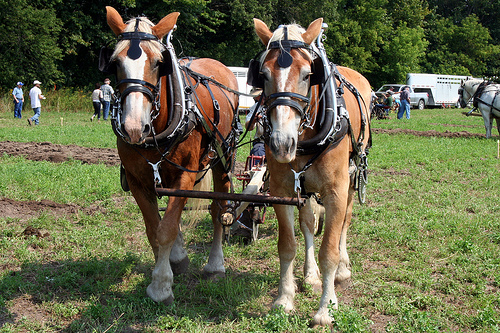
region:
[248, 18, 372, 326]
A tan and white horse.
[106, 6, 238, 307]
A brown and white horse.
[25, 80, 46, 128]
Person walking in field.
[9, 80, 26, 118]
A man wearing blue.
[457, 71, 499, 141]
A white work horse.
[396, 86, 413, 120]
A man in blue pants.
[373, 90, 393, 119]
A person sitting down.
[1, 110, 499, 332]
A green plow field.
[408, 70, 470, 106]
A white horse trailer.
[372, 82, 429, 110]
A silver colored truck.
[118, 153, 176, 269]
the brown and white leg of the horse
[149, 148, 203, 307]
the brown and white leg of the horse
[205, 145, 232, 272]
the brown and white leg of the horse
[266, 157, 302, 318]
the brown and white leg of the horse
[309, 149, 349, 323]
the brown and white leg of the horse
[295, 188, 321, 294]
the brown and white leg of the horse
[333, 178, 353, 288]
the brown and white leg of the horse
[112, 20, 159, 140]
the brown and white head of the horse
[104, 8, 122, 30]
the brown ear of the horse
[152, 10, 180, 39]
the brown ear of the horse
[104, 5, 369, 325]
draft horses pull a plow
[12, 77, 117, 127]
people walking from the field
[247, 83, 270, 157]
a man rides a plow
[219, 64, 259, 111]
a white trailer for moving horses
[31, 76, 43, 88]
man wears a white baseball cap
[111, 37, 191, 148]
both horses wear heavy padded collars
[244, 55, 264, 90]
blinkers near the eye lessens distractions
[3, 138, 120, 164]
a plowed section of land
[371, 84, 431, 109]
A pickup truck pulls a trailer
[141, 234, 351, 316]
all feet on both horses are white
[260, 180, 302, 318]
the leg of a horse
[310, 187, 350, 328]
the leg of a horse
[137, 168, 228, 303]
the legs of a horse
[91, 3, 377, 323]
two horses tied together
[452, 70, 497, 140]
a white horse in the background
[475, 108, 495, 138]
the leg of a horse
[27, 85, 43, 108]
a man in a white shirt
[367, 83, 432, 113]
a silver truck parked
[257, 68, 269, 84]
the eye of a horse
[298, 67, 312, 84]
the eye of a horse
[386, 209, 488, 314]
patches of grass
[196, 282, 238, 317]
a shadow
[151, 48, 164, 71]
left eye of the horse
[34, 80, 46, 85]
man wearing a white hat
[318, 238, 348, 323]
the leg of the horse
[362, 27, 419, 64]
the green bush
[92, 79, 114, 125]
people are walking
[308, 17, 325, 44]
the horses ear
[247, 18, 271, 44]
the ear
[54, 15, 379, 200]
two horses on the field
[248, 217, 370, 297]
front legs of the horse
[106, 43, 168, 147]
white blaze on horse face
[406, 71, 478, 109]
white horse trailer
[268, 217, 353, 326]
four white hooves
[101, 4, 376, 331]
two horses pulling a cart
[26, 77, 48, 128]
man walking on grass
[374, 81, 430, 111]
silver colored truck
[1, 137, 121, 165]
section of plowed dirt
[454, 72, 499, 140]
horse wearing a heavy harness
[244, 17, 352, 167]
heavy neck harness